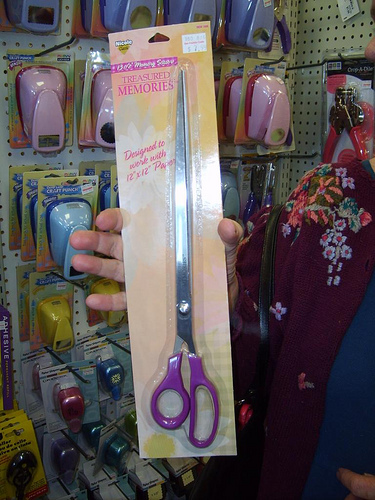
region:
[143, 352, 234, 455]
Purple handle to a pair of scissors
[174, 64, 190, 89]
Pointed to on a pair of scissors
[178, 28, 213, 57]
The price tag on a pair of scissors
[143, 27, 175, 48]
The hole to hang up a pair of scissors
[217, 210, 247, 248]
A person's right thumb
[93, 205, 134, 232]
A person's right pointer finger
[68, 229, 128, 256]
A person's right middle finger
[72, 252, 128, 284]
A person's right ring finger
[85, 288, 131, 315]
A person's right pinkie finger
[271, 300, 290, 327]
A flower on a sweater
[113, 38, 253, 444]
a very long pair of scissors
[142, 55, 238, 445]
a pair of purple scissors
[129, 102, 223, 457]
scissors designed to cut large pieces of paper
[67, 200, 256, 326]
a hand holding a product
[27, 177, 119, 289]
a craft punch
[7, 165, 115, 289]
a row of craft punches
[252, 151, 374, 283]
flowers on a sweater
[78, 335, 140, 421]
a blue design hole punch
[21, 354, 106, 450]
pink craft punches on a shelf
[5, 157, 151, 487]
craft punches on a display shelf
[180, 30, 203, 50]
white price sticker on box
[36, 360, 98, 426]
red hole puncher in package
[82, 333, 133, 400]
blue hole puncher in package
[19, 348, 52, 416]
red hole puncher in package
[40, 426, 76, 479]
purple hole puncher in package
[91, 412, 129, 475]
green hole puncher in package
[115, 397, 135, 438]
green hole puncher in package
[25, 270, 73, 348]
yellow hole puncher in package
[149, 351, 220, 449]
the purple handles of the scissors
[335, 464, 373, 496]
the finger of the hand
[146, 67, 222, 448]
THESE ARE SOME SCISSORS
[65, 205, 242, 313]
THIS IS HER HANDS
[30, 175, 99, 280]
THE IS A BLUE PRODUCT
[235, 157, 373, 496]
THIS IS PURPLE SWEATER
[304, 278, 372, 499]
THIS IS A BLUE SHIRT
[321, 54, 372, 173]
THE IS A RED ITEM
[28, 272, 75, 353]
THIS IS A YELLOW ITEM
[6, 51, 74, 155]
THIS IS A PINK ITEM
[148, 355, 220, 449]
THESE ARE THE HANDLE OF THE SCISSORS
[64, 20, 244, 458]
THE LADY IS HOLDING THE SCISSORS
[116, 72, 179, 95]
pink letters on package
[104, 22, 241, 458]
purple scissors inside packaging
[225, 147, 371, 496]
woman wearing purple jacket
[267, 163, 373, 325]
flowers on woman's jacket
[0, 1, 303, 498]
objects hanging on wall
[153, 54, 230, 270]
light shining on package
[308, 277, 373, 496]
woman's shirt is blue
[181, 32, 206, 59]
white tag on packaging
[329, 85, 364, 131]
metal part on object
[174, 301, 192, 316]
metal piece on object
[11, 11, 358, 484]
a scene inside a store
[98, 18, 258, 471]
a large purple scissors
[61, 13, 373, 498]
a person holding up the scissors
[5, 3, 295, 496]
items in the background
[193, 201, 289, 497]
a black purse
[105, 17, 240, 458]
long scissors in plastic